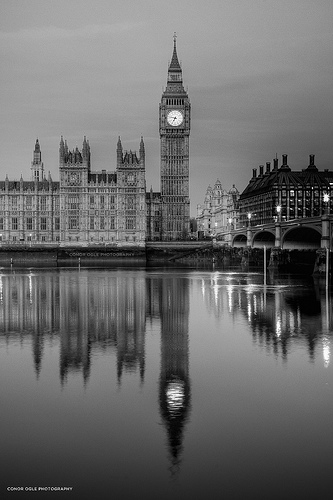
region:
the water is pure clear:
[222, 415, 286, 454]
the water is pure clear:
[251, 392, 303, 454]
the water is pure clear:
[177, 430, 242, 475]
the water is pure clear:
[214, 447, 270, 495]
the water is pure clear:
[184, 400, 244, 458]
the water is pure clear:
[216, 434, 254, 456]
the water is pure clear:
[204, 455, 219, 465]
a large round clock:
[157, 103, 194, 141]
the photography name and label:
[3, 474, 85, 494]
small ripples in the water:
[224, 301, 309, 375]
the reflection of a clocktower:
[152, 294, 211, 484]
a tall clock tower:
[156, 44, 221, 251]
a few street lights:
[200, 185, 332, 233]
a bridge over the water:
[223, 207, 330, 275]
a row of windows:
[3, 208, 143, 241]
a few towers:
[42, 120, 157, 246]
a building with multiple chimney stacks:
[226, 146, 325, 233]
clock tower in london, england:
[154, 27, 196, 238]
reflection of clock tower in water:
[155, 269, 195, 474]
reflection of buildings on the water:
[2, 270, 328, 466]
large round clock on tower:
[164, 103, 183, 125]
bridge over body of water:
[207, 190, 330, 249]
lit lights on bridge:
[206, 192, 330, 226]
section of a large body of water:
[2, 268, 327, 486]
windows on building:
[33, 168, 39, 177]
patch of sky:
[2, 3, 152, 106]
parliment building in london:
[1, 132, 151, 252]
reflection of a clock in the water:
[152, 370, 204, 421]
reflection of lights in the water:
[210, 269, 281, 312]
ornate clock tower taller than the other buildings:
[152, 31, 202, 245]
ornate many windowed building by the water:
[7, 132, 152, 248]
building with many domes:
[193, 175, 240, 242]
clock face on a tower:
[164, 107, 187, 131]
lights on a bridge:
[207, 196, 288, 231]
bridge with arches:
[229, 227, 290, 254]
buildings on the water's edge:
[10, 81, 304, 329]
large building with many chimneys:
[232, 146, 330, 215]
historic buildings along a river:
[7, 21, 324, 408]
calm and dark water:
[16, 273, 313, 468]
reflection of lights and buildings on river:
[12, 272, 324, 474]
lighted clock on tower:
[148, 87, 200, 140]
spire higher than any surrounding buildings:
[159, 25, 182, 81]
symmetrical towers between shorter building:
[54, 123, 145, 243]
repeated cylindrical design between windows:
[1, 166, 49, 245]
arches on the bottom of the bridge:
[206, 197, 321, 252]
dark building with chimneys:
[233, 145, 326, 216]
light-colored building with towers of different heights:
[192, 168, 235, 245]